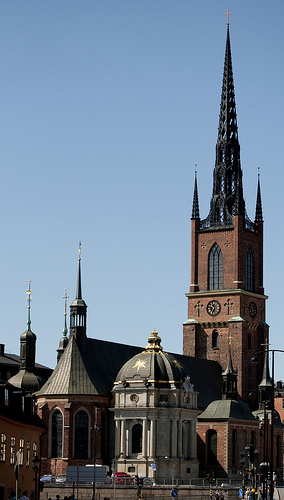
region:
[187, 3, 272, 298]
tall church steeple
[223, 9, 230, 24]
crucifix at the peak of steeple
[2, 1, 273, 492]
large red brick church with steeples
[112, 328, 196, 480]
domed building with white columns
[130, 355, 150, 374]
golden star on a dark roof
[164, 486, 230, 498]
pedestrians in a city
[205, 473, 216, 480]
small traffic lights near the road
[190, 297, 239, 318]
decorative masonry symbols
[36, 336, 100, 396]
steeply peaked roof on building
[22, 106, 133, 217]
clear blue sky on sunny day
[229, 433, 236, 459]
edge of a wall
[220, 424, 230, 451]
part of a wall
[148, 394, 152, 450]
edge of a pillar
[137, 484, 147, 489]
part of a wall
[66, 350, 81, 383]
part of the roof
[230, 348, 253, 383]
edge of a building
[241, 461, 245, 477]
part of the light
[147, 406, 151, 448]
part of a pillar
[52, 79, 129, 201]
the sky is clear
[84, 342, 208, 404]
a dome shaped roof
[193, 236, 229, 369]
a red and tiled building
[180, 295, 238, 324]
a clock between two crosees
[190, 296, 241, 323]
two big crosses on the wall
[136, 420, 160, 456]
the columns are white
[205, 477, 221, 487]
the traffic light is green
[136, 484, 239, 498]
people at the sidewalk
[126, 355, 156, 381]
a gold star on roof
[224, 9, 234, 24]
a cross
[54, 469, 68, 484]
a car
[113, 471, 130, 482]
a red car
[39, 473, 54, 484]
a blue car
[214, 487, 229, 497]
two people standing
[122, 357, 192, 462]
a building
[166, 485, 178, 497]
a person standing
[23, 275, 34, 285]
a gold cross on the building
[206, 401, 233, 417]
the roof on the building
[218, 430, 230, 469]
a brick building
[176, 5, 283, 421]
THE TOWER IS TALL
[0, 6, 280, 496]
THE BUILDING IS BIG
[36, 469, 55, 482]
THE CAR IS BLUE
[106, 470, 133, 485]
THE CAR IS RED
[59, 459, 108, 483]
THE SIGN IS SILVER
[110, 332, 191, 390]
THE DOME IS BLACK AND GOLD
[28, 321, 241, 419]
THE ROOF IS BLACK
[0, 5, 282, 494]
THE BUILDING IS BRICK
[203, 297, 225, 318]
THE CLOCK IS BLACK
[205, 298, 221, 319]
TH CLOCK IS ON THE TOWER